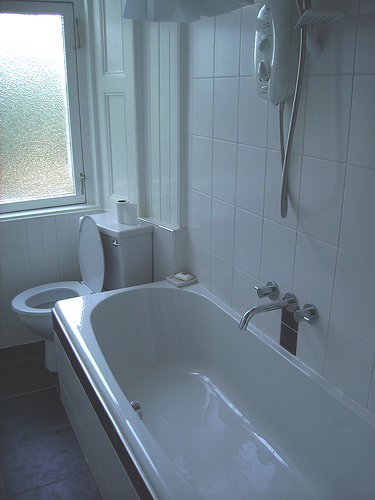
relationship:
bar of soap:
[155, 271, 195, 285] [166, 264, 203, 275]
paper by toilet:
[108, 191, 140, 216] [17, 249, 116, 329]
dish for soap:
[156, 269, 206, 299] [166, 264, 203, 275]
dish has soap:
[156, 269, 206, 299] [166, 264, 203, 275]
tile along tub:
[32, 397, 93, 453] [239, 275, 297, 330]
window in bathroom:
[10, 52, 75, 191] [28, 86, 283, 487]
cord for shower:
[251, 118, 312, 185] [235, 34, 311, 122]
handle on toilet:
[97, 235, 131, 249] [17, 249, 116, 329]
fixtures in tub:
[246, 274, 336, 350] [239, 275, 297, 330]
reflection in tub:
[141, 349, 228, 415] [239, 275, 297, 330]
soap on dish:
[166, 264, 203, 275] [156, 269, 206, 299]